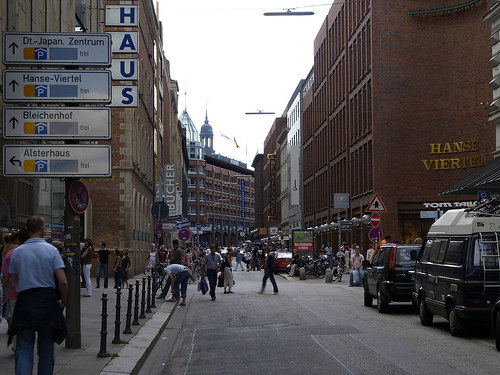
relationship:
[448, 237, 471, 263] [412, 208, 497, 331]
window on van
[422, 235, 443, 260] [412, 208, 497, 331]
window on van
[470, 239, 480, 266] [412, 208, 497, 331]
window on van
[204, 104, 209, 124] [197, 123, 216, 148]
steeple on dome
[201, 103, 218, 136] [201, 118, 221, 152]
steeple on dome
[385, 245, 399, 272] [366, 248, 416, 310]
taillight on jeep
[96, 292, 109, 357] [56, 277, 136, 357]
pole lining sidewalk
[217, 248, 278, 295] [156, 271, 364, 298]
people crossing street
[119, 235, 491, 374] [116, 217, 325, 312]
street with people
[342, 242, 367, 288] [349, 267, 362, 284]
man holding bag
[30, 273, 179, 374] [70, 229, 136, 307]
sidewalk with people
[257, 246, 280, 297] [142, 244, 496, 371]
person crossing crossing street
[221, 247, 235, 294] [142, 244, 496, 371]
person crossing crossing street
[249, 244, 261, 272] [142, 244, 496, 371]
person crossing crossing street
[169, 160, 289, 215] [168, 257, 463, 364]
building at end of street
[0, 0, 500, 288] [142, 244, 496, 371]
building on side of street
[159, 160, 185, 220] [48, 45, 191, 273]
banner on side of building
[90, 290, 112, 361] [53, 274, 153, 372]
pole on sidewalk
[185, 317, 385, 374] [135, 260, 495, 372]
blacktop on street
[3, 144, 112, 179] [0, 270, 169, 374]
direction sign above sidewalk